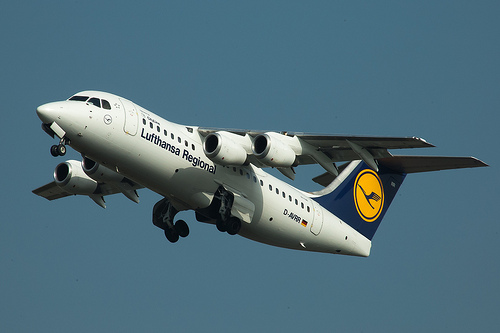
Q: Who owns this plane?
A: Lufthansa.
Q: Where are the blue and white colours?
A: On the plain.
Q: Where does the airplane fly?
A: In the sky.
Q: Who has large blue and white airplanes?
A: Lufthansa Regional.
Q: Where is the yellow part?
A: The tail.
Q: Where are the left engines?
A: Under the left wing.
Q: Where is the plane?
A: In the air.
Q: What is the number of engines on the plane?
A: 4.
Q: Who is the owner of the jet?
A: Lufthansa Regional.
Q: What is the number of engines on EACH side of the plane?
A: 2.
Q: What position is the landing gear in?
A: Down.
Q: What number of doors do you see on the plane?
A: 2.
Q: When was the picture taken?
A: In the daytime.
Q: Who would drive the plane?
A: A pilot.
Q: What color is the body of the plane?
A: White.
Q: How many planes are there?
A: 1.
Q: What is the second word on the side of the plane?
A: Regional.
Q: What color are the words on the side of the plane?
A: Black.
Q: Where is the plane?
A: In the air.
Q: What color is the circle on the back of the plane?
A: Yellow.